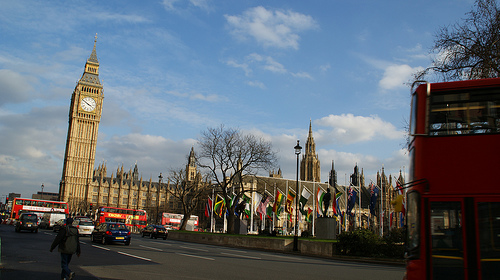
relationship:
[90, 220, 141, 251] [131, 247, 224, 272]
car on road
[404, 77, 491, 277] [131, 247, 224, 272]
bus on road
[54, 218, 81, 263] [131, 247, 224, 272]
person on road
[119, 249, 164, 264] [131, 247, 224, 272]
line on road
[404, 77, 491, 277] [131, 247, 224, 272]
bus near road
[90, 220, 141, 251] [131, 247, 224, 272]
car driving down road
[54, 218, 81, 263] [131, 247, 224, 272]
person walking in road